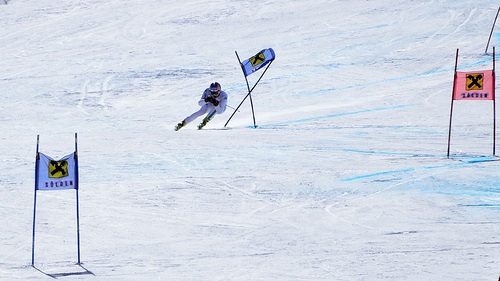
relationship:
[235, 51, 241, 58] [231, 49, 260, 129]
edge of post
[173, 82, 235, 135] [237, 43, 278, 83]
skier rounding flag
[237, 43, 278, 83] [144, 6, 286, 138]
flag on snow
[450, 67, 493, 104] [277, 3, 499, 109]
flag in snow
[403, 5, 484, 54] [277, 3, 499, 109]
tracks in snow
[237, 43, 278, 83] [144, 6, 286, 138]
flag in snow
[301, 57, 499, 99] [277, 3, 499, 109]
line in snow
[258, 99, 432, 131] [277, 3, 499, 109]
line in snow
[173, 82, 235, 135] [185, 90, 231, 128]
skier with outfit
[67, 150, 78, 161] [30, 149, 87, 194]
edge of sign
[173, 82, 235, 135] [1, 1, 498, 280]
skier going down hill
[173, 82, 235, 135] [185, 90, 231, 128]
skier wearing outfit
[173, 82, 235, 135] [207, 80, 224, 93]
skier wearing helmet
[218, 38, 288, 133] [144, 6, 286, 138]
markder on snow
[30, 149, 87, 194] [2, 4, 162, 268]
sign in snow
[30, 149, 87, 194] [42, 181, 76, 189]
sign has lettering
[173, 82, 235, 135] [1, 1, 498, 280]
person skiing down hill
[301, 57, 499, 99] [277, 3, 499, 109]
line over snow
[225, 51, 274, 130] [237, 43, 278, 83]
poles holding up flag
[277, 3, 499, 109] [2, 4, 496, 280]
snow over ground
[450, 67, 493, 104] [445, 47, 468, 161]
flag on pole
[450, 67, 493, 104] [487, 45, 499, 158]
flag on pole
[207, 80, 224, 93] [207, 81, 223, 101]
helmet on head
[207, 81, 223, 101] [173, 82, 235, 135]
head of person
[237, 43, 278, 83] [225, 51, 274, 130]
flag stuck on poles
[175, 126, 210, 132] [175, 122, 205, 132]
skiis on feet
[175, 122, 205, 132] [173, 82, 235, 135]
feet of person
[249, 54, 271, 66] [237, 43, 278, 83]
logo on flag